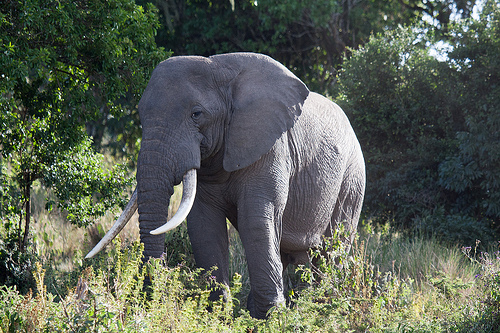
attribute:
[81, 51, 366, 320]
elephant — grey, calm, adult, standing, bothered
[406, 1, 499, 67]
patch of sky — blue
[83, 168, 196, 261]
tusks — ivory, white, pointed, curved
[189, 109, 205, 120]
eye — black, small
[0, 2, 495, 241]
trees — heavily wooded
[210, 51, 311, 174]
ear — grey, large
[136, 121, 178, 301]
trunk — down, wrinkled, long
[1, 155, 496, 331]
grass — green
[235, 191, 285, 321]
leg — grey, thick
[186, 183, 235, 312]
leg — grey